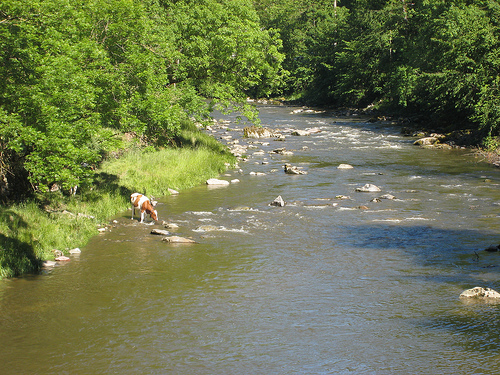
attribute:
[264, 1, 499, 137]
forest — lush, green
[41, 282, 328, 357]
water — clear 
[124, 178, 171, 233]
cow — white and black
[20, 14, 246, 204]
tree — bright green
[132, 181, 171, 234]
cow — small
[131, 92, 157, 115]
leaves — green 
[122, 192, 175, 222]
cow — white, brown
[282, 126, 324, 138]
rock — long 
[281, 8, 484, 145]
trees — darker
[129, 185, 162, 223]
cow — small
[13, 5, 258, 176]
leaves — green